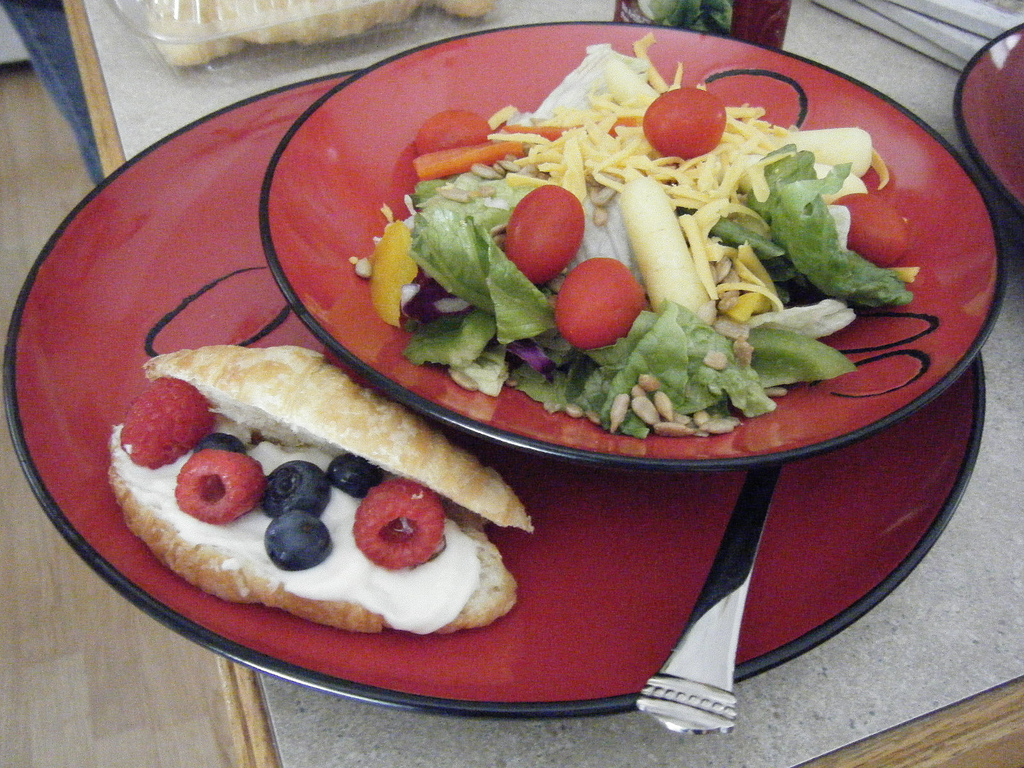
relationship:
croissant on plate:
[108, 342, 536, 630] [2, 68, 986, 715]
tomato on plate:
[506, 180, 580, 280] [257, 18, 1011, 468]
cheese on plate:
[676, 208, 720, 295] [257, 19, 1012, 468]